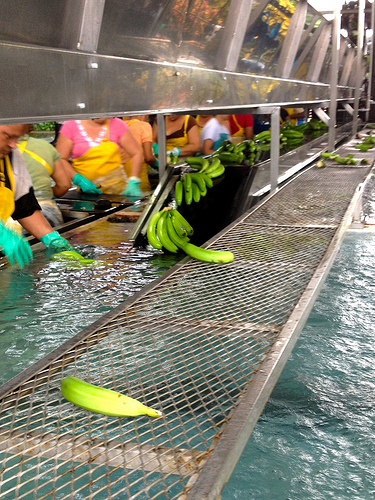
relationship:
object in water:
[125, 378, 334, 438] [263, 241, 369, 495]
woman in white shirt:
[199, 113, 229, 155] [200, 118, 230, 147]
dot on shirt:
[75, 119, 82, 124] [59, 117, 128, 155]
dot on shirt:
[81, 131, 87, 135] [59, 117, 128, 155]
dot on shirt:
[85, 137, 93, 141] [59, 117, 128, 155]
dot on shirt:
[100, 130, 106, 135] [59, 117, 128, 155]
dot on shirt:
[78, 123, 84, 128] [59, 117, 128, 155]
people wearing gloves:
[2, 114, 60, 267] [1, 217, 86, 274]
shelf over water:
[1, 127, 373, 499] [0, 167, 373, 498]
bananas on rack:
[169, 164, 211, 207] [0, 216, 365, 495]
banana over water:
[51, 371, 165, 427] [0, 167, 373, 498]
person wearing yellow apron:
[53, 118, 144, 199] [72, 128, 127, 193]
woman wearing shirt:
[0, 121, 71, 269] [57, 118, 124, 156]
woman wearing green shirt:
[15, 120, 72, 232] [15, 134, 60, 197]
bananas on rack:
[169, 151, 244, 208] [8, 263, 296, 498]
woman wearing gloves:
[0, 121, 71, 269] [0, 220, 73, 269]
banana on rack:
[51, 371, 165, 427] [4, 405, 88, 482]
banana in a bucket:
[171, 206, 193, 233] [143, 158, 258, 237]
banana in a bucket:
[170, 213, 186, 238] [143, 158, 258, 237]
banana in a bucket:
[155, 211, 179, 253] [143, 158, 258, 237]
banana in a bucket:
[146, 207, 164, 249] [143, 158, 258, 237]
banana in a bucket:
[165, 214, 185, 246] [143, 158, 258, 237]